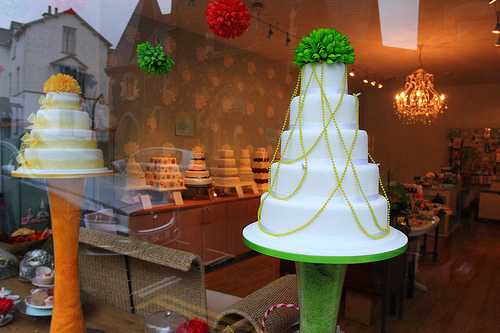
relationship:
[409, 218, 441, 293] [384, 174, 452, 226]
table covered in objects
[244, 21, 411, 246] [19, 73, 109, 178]
cake sideways cake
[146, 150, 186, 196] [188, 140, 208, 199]
cake sideways cake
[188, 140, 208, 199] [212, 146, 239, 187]
cake sideways cake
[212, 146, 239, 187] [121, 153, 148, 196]
cake sideways cake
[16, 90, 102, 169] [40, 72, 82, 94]
cake have adornment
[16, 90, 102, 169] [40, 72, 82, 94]
cake has adornment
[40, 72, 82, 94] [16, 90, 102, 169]
adornment over cake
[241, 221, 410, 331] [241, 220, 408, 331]
table has green white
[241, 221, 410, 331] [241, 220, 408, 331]
table have green white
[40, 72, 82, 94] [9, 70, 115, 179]
adornment on cake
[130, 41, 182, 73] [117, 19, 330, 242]
adornment hanging from wall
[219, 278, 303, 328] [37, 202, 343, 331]
arm on chair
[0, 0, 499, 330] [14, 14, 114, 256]
reflection on building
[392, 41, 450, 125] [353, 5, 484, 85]
chandelier hanging from ceiling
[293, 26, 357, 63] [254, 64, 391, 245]
adornment on top of cake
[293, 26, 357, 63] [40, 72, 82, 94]
adornment match adornment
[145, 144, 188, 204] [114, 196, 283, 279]
cakes on cabinet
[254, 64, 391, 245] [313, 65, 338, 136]
cake has beads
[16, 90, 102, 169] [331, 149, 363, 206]
cake has beads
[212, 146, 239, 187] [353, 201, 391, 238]
cake has beads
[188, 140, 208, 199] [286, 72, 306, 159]
cake has beads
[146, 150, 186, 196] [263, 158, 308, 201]
cake has beads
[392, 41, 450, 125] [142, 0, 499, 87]
chandelier hangs from ceiling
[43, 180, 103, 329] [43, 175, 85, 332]
base on orange pedestal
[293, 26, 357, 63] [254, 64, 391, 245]
adornment on cake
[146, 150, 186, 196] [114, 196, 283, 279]
cake on cabinet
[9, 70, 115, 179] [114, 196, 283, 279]
cake on cabinet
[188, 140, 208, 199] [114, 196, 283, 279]
cake on cabinet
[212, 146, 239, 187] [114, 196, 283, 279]
cake on cabinet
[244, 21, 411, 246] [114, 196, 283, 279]
cake on cabinet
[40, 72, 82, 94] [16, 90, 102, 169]
adornment on cake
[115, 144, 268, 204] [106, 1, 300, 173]
cakes against wall